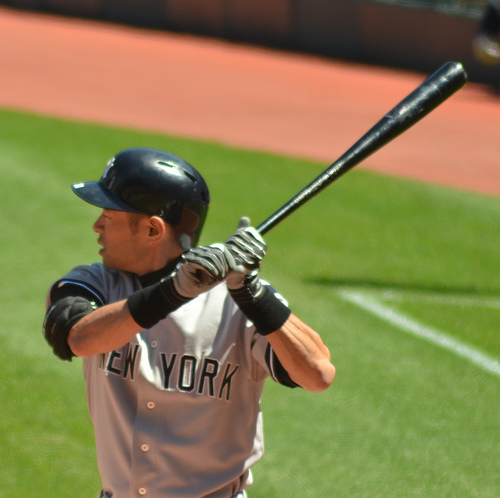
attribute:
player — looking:
[44, 147, 335, 495]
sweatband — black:
[127, 274, 196, 329]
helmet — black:
[72, 147, 209, 252]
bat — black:
[201, 60, 467, 287]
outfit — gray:
[43, 260, 297, 496]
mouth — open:
[98, 236, 110, 259]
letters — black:
[98, 341, 240, 403]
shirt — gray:
[47, 260, 299, 497]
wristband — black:
[126, 274, 186, 331]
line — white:
[334, 283, 497, 380]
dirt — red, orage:
[2, 11, 498, 197]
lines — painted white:
[336, 278, 498, 379]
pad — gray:
[14, 3, 497, 83]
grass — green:
[4, 110, 497, 487]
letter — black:
[217, 360, 240, 401]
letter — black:
[198, 356, 219, 396]